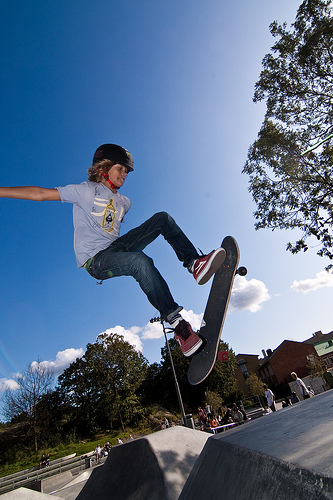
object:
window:
[243, 372, 251, 381]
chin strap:
[96, 167, 118, 190]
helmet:
[93, 143, 135, 173]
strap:
[96, 165, 120, 190]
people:
[221, 411, 233, 424]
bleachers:
[205, 416, 251, 433]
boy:
[0, 142, 227, 358]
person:
[39, 454, 47, 469]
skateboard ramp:
[177, 436, 333, 500]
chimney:
[266, 348, 273, 357]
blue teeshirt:
[53, 181, 131, 268]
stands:
[0, 404, 264, 500]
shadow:
[158, 442, 200, 480]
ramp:
[210, 385, 333, 478]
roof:
[313, 338, 333, 356]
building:
[232, 331, 333, 401]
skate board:
[187, 235, 247, 386]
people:
[239, 400, 248, 421]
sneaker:
[173, 317, 204, 358]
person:
[210, 414, 217, 428]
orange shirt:
[208, 416, 211, 423]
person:
[262, 383, 277, 412]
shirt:
[265, 389, 275, 407]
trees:
[160, 327, 237, 410]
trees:
[245, 367, 268, 411]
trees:
[204, 388, 224, 417]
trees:
[56, 331, 147, 434]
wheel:
[219, 350, 229, 362]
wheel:
[238, 265, 247, 277]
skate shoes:
[191, 247, 228, 286]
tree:
[240, 0, 332, 278]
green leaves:
[310, 25, 327, 33]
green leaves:
[272, 59, 294, 72]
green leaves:
[297, 81, 323, 99]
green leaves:
[274, 143, 295, 156]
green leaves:
[292, 196, 320, 210]